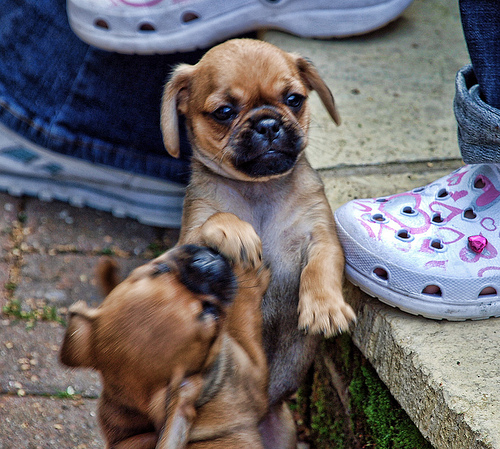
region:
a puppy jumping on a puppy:
[57, 39, 356, 447]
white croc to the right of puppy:
[328, 161, 498, 322]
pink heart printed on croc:
[378, 189, 429, 235]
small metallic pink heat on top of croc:
[468, 234, 488, 254]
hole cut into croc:
[421, 283, 443, 298]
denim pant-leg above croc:
[453, 0, 498, 163]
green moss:
[300, 339, 434, 447]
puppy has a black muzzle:
[228, 115, 297, 177]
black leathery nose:
[254, 118, 278, 138]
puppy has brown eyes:
[286, 93, 303, 107]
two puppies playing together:
[47, 49, 358, 447]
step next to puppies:
[220, 28, 487, 448]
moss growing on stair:
[315, 360, 446, 447]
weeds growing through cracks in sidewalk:
[6, 198, 169, 353]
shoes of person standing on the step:
[72, 2, 499, 322]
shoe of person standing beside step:
[3, 127, 196, 235]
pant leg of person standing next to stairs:
[5, 0, 192, 183]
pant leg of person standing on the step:
[451, 5, 499, 166]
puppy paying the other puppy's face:
[154, 52, 355, 438]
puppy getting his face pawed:
[63, 248, 279, 447]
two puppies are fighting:
[97, 58, 352, 447]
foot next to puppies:
[338, 153, 499, 324]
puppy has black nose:
[247, 114, 284, 138]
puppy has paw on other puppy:
[183, 204, 263, 284]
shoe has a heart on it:
[462, 233, 491, 254]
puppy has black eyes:
[213, 84, 307, 126]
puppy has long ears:
[154, 61, 209, 161]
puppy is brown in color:
[62, 247, 257, 443]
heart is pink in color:
[467, 232, 487, 254]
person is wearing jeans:
[452, 5, 499, 142]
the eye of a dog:
[211, 103, 233, 119]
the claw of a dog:
[299, 318, 310, 334]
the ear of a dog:
[310, 68, 337, 113]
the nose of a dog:
[255, 118, 286, 145]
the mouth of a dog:
[255, 146, 285, 164]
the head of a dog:
[191, 47, 314, 173]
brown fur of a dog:
[120, 314, 164, 361]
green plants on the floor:
[367, 391, 388, 421]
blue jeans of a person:
[45, 67, 106, 135]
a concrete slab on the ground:
[7, 335, 52, 375]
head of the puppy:
[151, 50, 345, 187]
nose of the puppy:
[253, 108, 298, 148]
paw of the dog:
[288, 268, 364, 340]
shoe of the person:
[338, 170, 493, 296]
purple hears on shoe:
[363, 183, 442, 250]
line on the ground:
[8, 368, 53, 420]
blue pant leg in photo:
[14, 44, 115, 139]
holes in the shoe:
[361, 189, 464, 258]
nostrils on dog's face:
[244, 108, 294, 145]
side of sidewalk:
[359, 348, 454, 415]